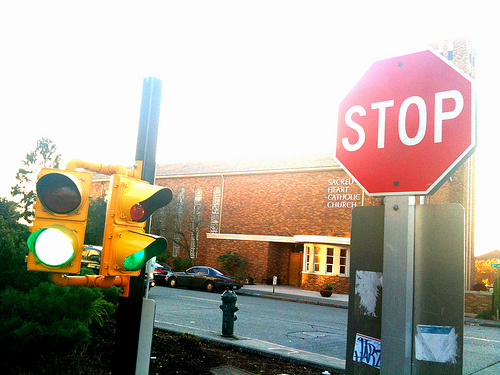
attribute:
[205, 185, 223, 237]
window — stained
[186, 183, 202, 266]
window — stained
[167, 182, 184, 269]
window — stained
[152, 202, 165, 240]
window — stained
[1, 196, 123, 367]
shrub — green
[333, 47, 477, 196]
sign — red and white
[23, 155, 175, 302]
traffic light — yellow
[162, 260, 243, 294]
car — black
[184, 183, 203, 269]
window — long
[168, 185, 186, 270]
window — long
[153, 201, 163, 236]
window — long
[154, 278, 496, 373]
roadway — paved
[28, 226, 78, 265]
traffic signal — green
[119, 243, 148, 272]
traffic signal — green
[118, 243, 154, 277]
traffic signal — green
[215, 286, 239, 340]
fire hydrant — green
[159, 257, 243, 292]
car — dark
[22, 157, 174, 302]
lights — traffic signal